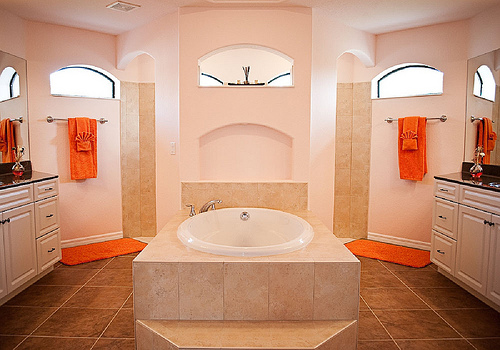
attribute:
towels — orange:
[396, 113, 431, 183]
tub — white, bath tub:
[183, 197, 310, 259]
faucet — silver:
[179, 194, 229, 214]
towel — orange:
[397, 102, 439, 183]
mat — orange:
[347, 216, 438, 284]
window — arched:
[373, 66, 464, 104]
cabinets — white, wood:
[432, 185, 499, 275]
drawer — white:
[426, 175, 463, 201]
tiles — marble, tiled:
[370, 255, 439, 339]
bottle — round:
[467, 134, 491, 180]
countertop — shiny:
[439, 150, 498, 190]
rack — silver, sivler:
[382, 102, 456, 127]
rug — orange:
[348, 231, 426, 268]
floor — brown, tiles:
[377, 260, 421, 341]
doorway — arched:
[340, 52, 395, 227]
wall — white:
[438, 44, 478, 140]